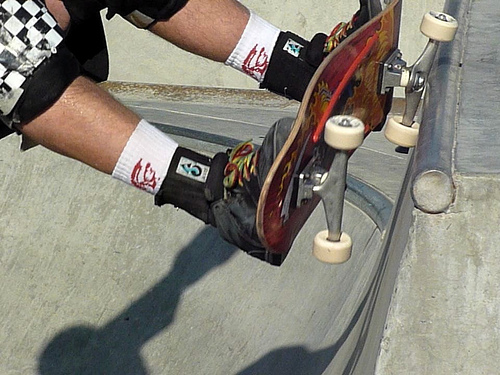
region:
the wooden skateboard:
[254, 1, 454, 256]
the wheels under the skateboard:
[309, 9, 458, 265]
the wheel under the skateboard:
[322, 114, 362, 147]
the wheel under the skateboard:
[313, 229, 351, 264]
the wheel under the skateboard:
[384, 114, 418, 148]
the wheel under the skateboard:
[419, 12, 457, 42]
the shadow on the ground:
[36, 148, 419, 374]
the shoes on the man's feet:
[152, 0, 381, 266]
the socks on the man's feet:
[110, 10, 280, 196]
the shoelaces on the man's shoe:
[220, 137, 260, 199]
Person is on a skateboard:
[0, 0, 458, 266]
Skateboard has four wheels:
[310, 6, 470, 266]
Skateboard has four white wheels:
[314, 5, 461, 267]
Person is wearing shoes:
[202, 0, 387, 264]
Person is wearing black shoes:
[205, 2, 390, 272]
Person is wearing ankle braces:
[145, 26, 328, 236]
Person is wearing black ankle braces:
[149, 26, 329, 234]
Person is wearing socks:
[110, 10, 285, 197]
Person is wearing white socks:
[110, 9, 285, 202]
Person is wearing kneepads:
[0, 0, 198, 142]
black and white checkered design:
[8, 10, 59, 54]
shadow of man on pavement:
[49, 304, 171, 356]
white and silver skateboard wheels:
[330, 108, 377, 289]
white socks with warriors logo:
[218, 31, 275, 78]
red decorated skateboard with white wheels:
[240, 13, 454, 218]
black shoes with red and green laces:
[168, 110, 286, 254]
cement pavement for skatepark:
[30, 184, 417, 354]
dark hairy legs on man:
[159, 0, 246, 43]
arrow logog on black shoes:
[165, 157, 216, 187]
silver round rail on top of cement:
[408, 63, 452, 247]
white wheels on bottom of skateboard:
[307, 5, 465, 264]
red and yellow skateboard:
[252, 0, 462, 267]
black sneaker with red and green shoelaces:
[205, 110, 290, 272]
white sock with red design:
[108, 108, 182, 208]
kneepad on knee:
[1, 0, 86, 145]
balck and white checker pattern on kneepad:
[1, 1, 62, 118]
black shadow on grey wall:
[8, 195, 388, 374]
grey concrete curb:
[346, 1, 498, 369]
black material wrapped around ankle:
[149, 146, 217, 228]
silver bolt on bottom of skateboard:
[274, 144, 331, 230]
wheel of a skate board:
[325, 110, 375, 160]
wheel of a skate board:
[315, 215, 355, 260]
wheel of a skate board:
[383, 102, 419, 148]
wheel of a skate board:
[411, 8, 467, 51]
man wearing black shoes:
[172, 127, 282, 252]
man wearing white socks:
[106, 125, 167, 196]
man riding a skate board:
[175, 0, 452, 280]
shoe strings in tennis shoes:
[215, 140, 260, 195]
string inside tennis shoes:
[316, 15, 353, 41]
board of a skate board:
[258, 184, 297, 251]